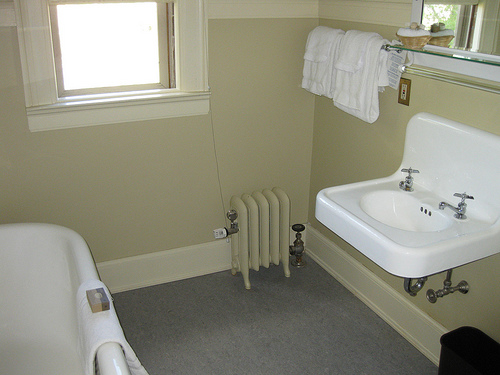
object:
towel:
[297, 23, 392, 124]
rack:
[395, 61, 499, 94]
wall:
[309, 0, 499, 367]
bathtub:
[0, 218, 129, 374]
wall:
[0, 0, 320, 288]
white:
[429, 122, 461, 189]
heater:
[212, 187, 293, 290]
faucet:
[438, 192, 474, 219]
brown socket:
[396, 78, 411, 106]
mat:
[66, 280, 147, 374]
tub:
[0, 220, 129, 375]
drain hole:
[420, 206, 432, 216]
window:
[51, 0, 168, 95]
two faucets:
[397, 168, 474, 220]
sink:
[356, 187, 456, 233]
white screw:
[213, 227, 228, 239]